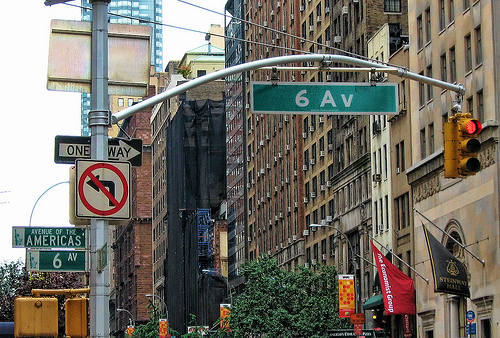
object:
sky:
[0, 0, 233, 280]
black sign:
[52, 135, 143, 167]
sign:
[250, 81, 400, 115]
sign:
[12, 226, 88, 248]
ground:
[375, 144, 388, 152]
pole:
[364, 231, 429, 282]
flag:
[369, 239, 415, 316]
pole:
[111, 54, 465, 124]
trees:
[0, 260, 91, 327]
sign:
[72, 158, 132, 220]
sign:
[24, 247, 89, 273]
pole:
[256, 66, 398, 73]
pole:
[89, 0, 110, 338]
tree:
[123, 252, 342, 338]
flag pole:
[412, 208, 486, 268]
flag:
[421, 222, 471, 298]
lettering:
[440, 277, 468, 290]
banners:
[124, 273, 355, 336]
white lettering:
[377, 253, 394, 313]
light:
[63, 297, 87, 338]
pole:
[84, 1, 119, 336]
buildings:
[108, 0, 500, 338]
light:
[441, 111, 482, 179]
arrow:
[59, 141, 141, 162]